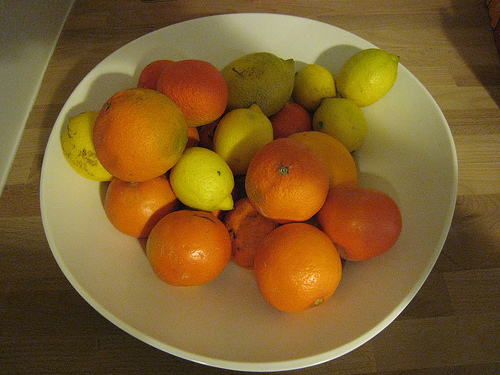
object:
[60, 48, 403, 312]
group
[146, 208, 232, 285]
orange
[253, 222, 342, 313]
orange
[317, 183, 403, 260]
orange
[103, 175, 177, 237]
orange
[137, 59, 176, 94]
orange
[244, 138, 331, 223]
orange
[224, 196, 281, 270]
orange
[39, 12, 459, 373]
plate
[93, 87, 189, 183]
orange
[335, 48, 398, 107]
lemon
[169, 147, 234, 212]
lemon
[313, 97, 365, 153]
lemon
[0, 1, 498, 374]
table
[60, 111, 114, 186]
lemon